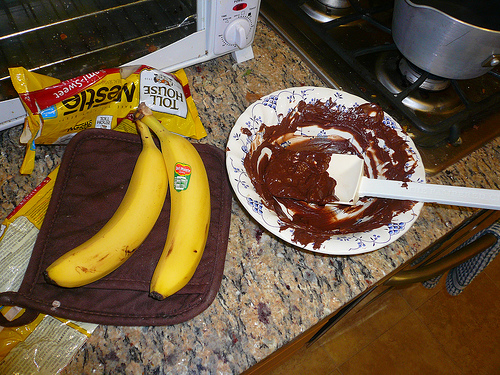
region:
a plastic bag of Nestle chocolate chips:
[5, 65, 215, 162]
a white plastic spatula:
[258, 154, 496, 220]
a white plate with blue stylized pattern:
[222, 85, 428, 259]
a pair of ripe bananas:
[40, 110, 215, 300]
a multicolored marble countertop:
[6, 16, 493, 373]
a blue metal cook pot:
[368, 4, 498, 130]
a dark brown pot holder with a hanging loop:
[2, 133, 231, 333]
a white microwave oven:
[1, 0, 262, 130]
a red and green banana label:
[170, 161, 191, 191]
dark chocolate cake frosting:
[245, 97, 420, 253]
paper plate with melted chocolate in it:
[230, 87, 417, 254]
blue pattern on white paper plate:
[233, 82, 416, 251]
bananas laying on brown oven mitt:
[58, 114, 202, 294]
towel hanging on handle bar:
[441, 240, 498, 294]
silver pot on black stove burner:
[380, 2, 498, 111]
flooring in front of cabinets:
[307, 268, 498, 368]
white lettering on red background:
[49, 71, 114, 99]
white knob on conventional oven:
[223, 21, 255, 46]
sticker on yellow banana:
[173, 160, 195, 196]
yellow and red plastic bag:
[8, 59, 205, 143]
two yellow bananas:
[50, 119, 212, 297]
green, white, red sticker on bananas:
[169, 158, 190, 191]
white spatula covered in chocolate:
[260, 145, 498, 218]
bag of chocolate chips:
[10, 55, 195, 145]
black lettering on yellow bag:
[55, 82, 134, 121]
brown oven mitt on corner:
[2, 139, 231, 328]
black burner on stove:
[375, 44, 462, 114]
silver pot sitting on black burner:
[390, 4, 497, 81]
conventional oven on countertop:
[2, 1, 254, 133]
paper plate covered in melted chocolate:
[240, 77, 423, 254]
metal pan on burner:
[377, 2, 497, 129]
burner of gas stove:
[315, 3, 496, 151]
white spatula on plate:
[229, 87, 492, 252]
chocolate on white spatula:
[266, 146, 498, 216]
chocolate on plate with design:
[227, 83, 419, 255]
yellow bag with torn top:
[10, 66, 204, 169]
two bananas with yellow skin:
[42, 106, 212, 296]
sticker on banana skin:
[144, 110, 209, 297]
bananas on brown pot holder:
[10, 106, 231, 326]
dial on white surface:
[214, 1, 264, 56]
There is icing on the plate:
[251, 90, 443, 252]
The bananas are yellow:
[28, 101, 208, 331]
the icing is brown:
[235, 112, 403, 244]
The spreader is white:
[268, 153, 383, 212]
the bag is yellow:
[1, 70, 206, 127]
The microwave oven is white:
[0, 12, 253, 124]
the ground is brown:
[282, 295, 486, 372]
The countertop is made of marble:
[21, 92, 488, 370]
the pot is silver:
[366, 9, 493, 76]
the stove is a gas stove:
[277, 18, 489, 151]